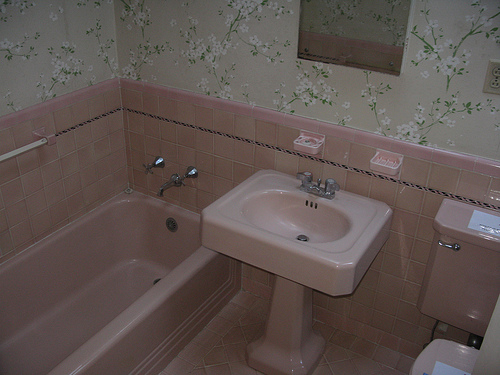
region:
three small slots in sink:
[300, 197, 320, 210]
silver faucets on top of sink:
[291, 167, 336, 198]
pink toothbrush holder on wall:
[290, 127, 325, 152]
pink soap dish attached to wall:
[370, 147, 406, 176]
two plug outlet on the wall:
[483, 57, 498, 95]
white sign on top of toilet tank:
[466, 207, 498, 240]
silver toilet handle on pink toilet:
[432, 237, 462, 254]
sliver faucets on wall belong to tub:
[139, 152, 199, 204]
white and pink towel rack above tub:
[1, 128, 56, 163]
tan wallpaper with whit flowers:
[167, 7, 257, 97]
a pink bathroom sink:
[199, 167, 394, 296]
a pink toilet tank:
[418, 197, 498, 337]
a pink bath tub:
[4, 186, 242, 372]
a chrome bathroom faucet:
[294, 167, 341, 204]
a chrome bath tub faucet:
[152, 172, 183, 201]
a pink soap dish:
[293, 127, 325, 159]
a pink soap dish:
[369, 147, 406, 181]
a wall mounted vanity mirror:
[299, 0, 411, 79]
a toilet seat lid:
[410, 340, 482, 373]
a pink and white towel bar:
[2, 128, 55, 166]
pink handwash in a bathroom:
[198, 165, 388, 371]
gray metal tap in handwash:
[295, 165, 335, 200]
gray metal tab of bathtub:
[141, 157, 198, 203]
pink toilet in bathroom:
[406, 195, 491, 370]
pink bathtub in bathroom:
[5, 186, 236, 371]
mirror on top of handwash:
[295, 0, 406, 75]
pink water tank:
[417, 195, 493, 331]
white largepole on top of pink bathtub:
[0, 125, 48, 162]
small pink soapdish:
[290, 127, 323, 152]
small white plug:
[477, 55, 498, 91]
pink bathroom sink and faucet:
[197, 158, 392, 297]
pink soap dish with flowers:
[365, 108, 408, 176]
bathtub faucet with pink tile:
[138, 142, 201, 208]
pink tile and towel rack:
[5, 127, 61, 166]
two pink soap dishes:
[290, 122, 403, 177]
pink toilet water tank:
[421, 189, 496, 341]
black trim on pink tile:
[411, 163, 438, 199]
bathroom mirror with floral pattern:
[278, 9, 427, 87]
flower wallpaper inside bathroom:
[127, 11, 257, 69]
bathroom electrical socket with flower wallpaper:
[434, 44, 498, 105]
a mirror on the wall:
[310, 7, 405, 71]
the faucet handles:
[290, 170, 333, 200]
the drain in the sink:
[290, 225, 313, 240]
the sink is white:
[209, 202, 369, 268]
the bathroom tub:
[32, 279, 139, 353]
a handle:
[12, 139, 53, 155]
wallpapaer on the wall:
[414, 52, 477, 117]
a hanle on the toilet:
[438, 235, 458, 256]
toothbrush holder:
[291, 133, 320, 152]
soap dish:
[370, 146, 405, 173]